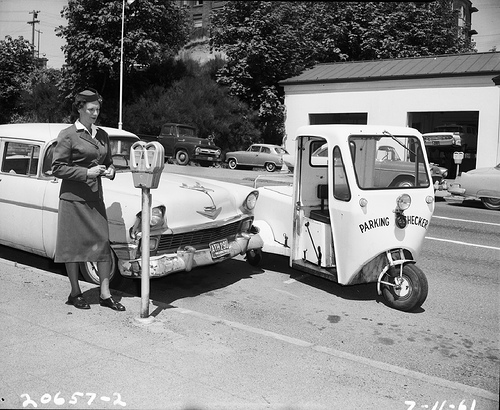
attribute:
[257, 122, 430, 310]
cart — small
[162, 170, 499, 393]
asphalt — dry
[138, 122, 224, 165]
truck — pick up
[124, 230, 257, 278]
bumper — heavy , chrome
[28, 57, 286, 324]
vehicle — parking checker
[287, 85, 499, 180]
wall — white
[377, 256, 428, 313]
wheel — black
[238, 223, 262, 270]
wheel — black